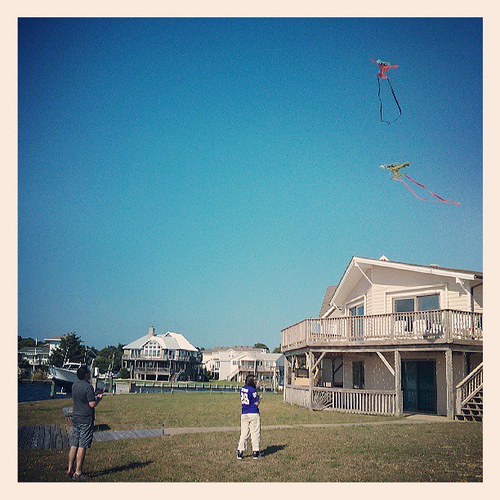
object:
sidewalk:
[20, 412, 448, 441]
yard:
[16, 366, 482, 483]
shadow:
[86, 453, 156, 476]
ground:
[25, 368, 483, 483]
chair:
[411, 318, 427, 335]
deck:
[309, 335, 481, 355]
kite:
[370, 56, 402, 124]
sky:
[18, 18, 480, 352]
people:
[238, 369, 265, 460]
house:
[278, 254, 482, 423]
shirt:
[71, 378, 97, 424]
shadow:
[252, 442, 286, 458]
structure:
[278, 258, 481, 418]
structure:
[121, 327, 203, 384]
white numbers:
[238, 392, 248, 407]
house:
[269, 245, 482, 420]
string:
[392, 173, 459, 209]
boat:
[50, 366, 103, 395]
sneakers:
[237, 450, 244, 459]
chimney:
[149, 325, 155, 336]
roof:
[123, 334, 194, 351]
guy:
[64, 365, 106, 485]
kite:
[379, 157, 461, 213]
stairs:
[454, 359, 487, 421]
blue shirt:
[239, 386, 260, 414]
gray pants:
[238, 412, 263, 449]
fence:
[280, 309, 482, 354]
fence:
[285, 379, 397, 416]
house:
[204, 343, 286, 387]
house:
[122, 324, 199, 384]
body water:
[17, 373, 244, 401]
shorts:
[67, 421, 94, 448]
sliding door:
[398, 357, 445, 414]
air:
[25, 49, 429, 473]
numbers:
[240, 388, 249, 406]